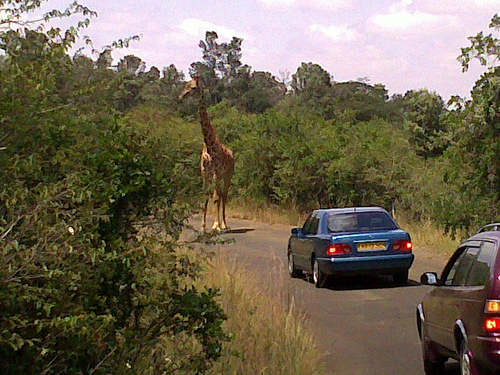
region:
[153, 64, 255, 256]
giraffe on the road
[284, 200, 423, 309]
car on the road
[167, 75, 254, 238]
a girrafe on the road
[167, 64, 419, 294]
a giraffe in front of a car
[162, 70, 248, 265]
a giraffe standing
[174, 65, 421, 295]
a giraffe in front of a blue car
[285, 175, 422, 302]
a blue car on the road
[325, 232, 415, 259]
the backlights on a car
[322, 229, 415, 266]
the break lights on a car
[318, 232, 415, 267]
break lights on a blue car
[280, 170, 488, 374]
a blue car in front of another car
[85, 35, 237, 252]
a giraffe standing next to trees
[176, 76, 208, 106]
head of a giraffe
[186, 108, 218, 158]
neck of a giraffe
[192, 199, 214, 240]
leg of a giraffe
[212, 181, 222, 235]
leg of a giraffe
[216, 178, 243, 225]
leg of a giraffe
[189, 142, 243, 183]
body of a giraffe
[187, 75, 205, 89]
ear of a giraffe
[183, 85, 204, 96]
eye of a giraffe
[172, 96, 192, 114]
mouth of a giraffe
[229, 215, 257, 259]
shadow of a giraffe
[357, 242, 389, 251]
Slim yellow rectangular license plate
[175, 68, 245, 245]
Giraffe standing on the asphalt path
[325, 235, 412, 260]
Red illuminated tail lights on the back of the car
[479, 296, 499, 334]
Left tail light of the red car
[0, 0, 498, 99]
Purple sky with white clouds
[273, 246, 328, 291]
Two left wheels of the blue car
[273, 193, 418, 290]
Blue four door car driving towards the giraffe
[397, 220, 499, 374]
Edge of a red car on the path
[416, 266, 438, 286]
Left side view mirror on the red car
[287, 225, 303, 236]
Left side view mirror of the blue car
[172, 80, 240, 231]
giraffe walking on land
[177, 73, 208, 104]
the head of the giraffe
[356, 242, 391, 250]
license plate on back of car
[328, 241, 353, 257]
left brake light on car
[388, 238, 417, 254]
right brake light on car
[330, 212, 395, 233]
window on back of car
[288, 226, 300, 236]
rearview mirror on car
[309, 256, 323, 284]
rear left tire on car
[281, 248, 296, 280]
black front tire on car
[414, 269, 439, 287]
rearview mirror on burgundy car